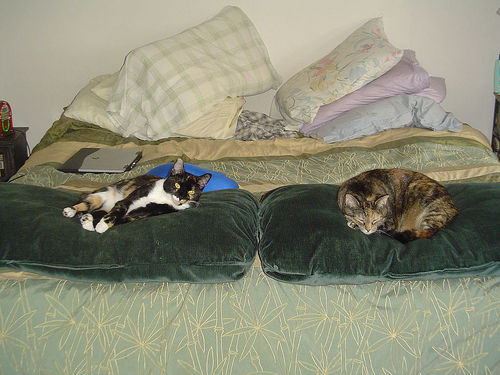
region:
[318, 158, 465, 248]
a calico cat on a pillow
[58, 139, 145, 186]
a laptop on the bed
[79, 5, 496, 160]
two stacks of pillows on the bed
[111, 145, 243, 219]
a blue pillow behind the cat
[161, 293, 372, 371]
a comforter with a floral design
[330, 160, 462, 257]
A cat is sleeping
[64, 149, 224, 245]
A cat looking at the camera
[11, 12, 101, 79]
a lavender wall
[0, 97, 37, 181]
a bed side table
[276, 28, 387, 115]
a pillow with a floral pillow case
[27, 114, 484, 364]
the cats are lying on the pillow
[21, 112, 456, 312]
two cats in front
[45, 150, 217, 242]
black and white cat laying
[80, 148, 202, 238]
cat laying down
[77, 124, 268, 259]
cat laying on pillow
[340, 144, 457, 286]
brown and black cat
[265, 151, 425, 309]
cat laying down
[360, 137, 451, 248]
cat laying on pillow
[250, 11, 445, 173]
stack of pillows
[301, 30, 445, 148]
purple and blue pillow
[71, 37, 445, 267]
cats laying on top of bed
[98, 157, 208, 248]
black and white kitty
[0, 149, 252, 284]
the left green pillow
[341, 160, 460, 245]
a brown multicolored cat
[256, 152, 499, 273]
the right green pillow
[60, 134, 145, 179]
this is a laptop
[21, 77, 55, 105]
this is a white wall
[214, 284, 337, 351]
these are yellow flowers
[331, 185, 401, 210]
these are cat ears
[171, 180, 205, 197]
these are cat eyes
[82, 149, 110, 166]
this is a logo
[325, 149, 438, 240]
cat on a pillow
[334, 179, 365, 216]
ear of the cat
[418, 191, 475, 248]
tail of the cat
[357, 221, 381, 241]
nose of the cat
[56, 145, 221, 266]
cat on the left pillow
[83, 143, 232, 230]
dark and light cat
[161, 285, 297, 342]
design on the blanket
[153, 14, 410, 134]
pillows in the background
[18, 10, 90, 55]
wall behind the pillow